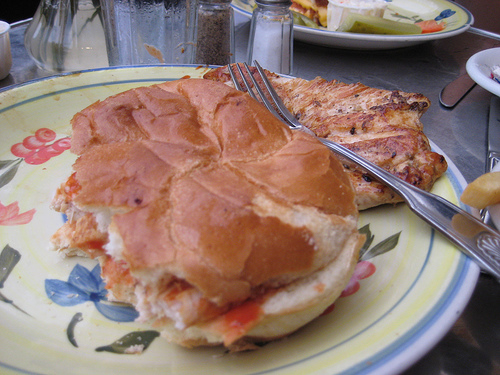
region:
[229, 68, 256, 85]
metal tines in a fork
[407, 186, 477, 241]
handle of a fork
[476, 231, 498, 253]
metal stamp on the fork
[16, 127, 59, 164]
pink painted flower on the plate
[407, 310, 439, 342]
blue trim around the plate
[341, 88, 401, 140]
a piece of grilled chicken breast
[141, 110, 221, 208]
soft kaiser roll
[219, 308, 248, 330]
tomato on a sanwich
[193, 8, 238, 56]
pepper shaker next to plate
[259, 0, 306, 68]
salt shaker sitting on table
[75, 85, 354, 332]
bread is on plate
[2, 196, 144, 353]
plate has floral design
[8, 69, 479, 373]
plate is round and yellow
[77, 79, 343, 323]
food is on the plate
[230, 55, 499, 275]
fork is on the plate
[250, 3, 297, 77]
salt shaker behind the food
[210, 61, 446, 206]
chicken is on the plate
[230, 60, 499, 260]
fork is very silver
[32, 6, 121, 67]
glass vase near food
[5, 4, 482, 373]
two plate on table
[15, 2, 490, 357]
plates of food on table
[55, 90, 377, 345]
eaten sandwich on flowered plate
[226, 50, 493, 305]
fork separating sandwich from grilled meat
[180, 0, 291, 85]
salt and pepper shakers behind plate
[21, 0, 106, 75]
bottom of glass vase with end of stem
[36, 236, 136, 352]
painted blue petals over a curved stem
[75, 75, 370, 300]
cracked and missing crust on bread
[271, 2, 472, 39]
slice of pickle on side of plate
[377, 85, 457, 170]
browned bits on edge of meat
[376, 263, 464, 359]
yellow and blue edging on plate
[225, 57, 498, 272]
fork with a logo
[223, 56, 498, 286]
a fork from a restaurant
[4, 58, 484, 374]
a blue and white plate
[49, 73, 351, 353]
a sandwich with a red sauce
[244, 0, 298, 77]
a salt shaker behind a plate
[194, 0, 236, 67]
a pepper shaker behind a plate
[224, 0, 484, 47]
a plate for another person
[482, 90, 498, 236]
a butter knife on the table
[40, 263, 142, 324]
representation of a blue flower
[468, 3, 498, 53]
the shiny edge of the table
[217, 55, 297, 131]
Fork on a piece of chicken.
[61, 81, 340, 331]
Sandwich on a plate.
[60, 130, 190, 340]
The sandwich is half eaten.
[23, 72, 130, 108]
Grease on the plate.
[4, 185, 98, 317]
Floral pattern on the plate.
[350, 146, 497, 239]
The fork is silver.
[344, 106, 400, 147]
The chicken is brown.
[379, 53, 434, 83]
The table is grey.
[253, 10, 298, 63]
Salt in the shaker.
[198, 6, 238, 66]
Pepper in the shaker.